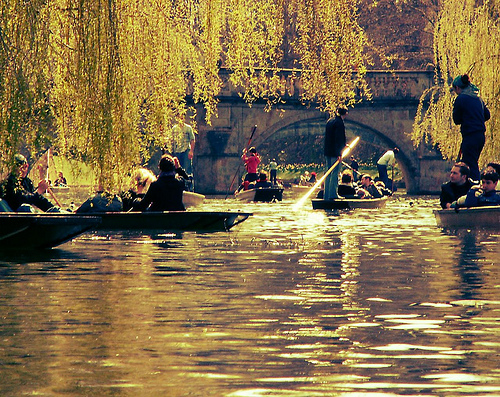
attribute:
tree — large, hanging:
[59, 17, 399, 139]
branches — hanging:
[204, 0, 280, 95]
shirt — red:
[242, 154, 262, 172]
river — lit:
[226, 241, 427, 375]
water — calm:
[149, 243, 430, 367]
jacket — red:
[245, 156, 256, 169]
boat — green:
[106, 210, 243, 235]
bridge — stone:
[140, 64, 488, 199]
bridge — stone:
[132, 65, 497, 212]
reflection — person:
[318, 210, 355, 343]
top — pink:
[240, 150, 260, 170]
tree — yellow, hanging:
[1, 0, 401, 205]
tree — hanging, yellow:
[399, 1, 485, 175]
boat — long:
[70, 209, 254, 231]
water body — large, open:
[1, 186, 483, 392]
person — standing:
[449, 72, 485, 181]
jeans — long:
[319, 160, 342, 200]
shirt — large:
[321, 113, 348, 162]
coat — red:
[244, 154, 258, 172]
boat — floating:
[77, 207, 255, 237]